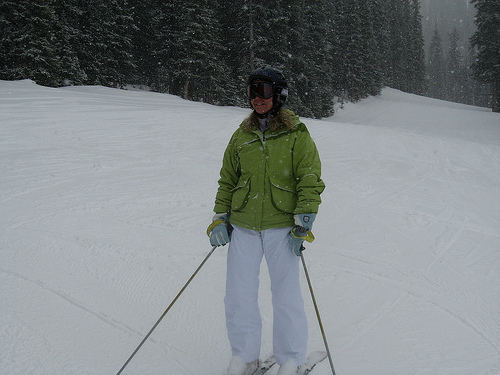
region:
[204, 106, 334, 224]
a green coat on a person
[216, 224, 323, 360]
white pants on a person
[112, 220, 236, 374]
a ski pole held in a hand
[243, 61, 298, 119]
a black helmet on a person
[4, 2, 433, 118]
a forest of pine trees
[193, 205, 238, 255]
a glove on a person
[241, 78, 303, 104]
goggles on a person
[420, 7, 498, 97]
snow falling in the distance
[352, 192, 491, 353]
tracks in the snow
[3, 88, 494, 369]
a white snowy slope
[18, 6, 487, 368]
A blistery winter day on the mountain.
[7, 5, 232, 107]
Evergreen trees growing in the woods.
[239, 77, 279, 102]
Ski mask for protecting her eyes.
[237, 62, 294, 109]
Black safety helmet for protection.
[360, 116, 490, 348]
Ground covered in layers of fallen snow.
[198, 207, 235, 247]
Light blue snow glove for keeping her hands warm.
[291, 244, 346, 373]
Tall ski pole to help get through the snow.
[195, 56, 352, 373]
Woman standing on two skis.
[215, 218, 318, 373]
Woman wearing white snow pants.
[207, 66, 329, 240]
Woman wearing puffy green snow jacket.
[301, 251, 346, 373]
a long trekking pole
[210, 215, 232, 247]
a gray ski glove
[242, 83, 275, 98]
dark black goggles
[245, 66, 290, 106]
a dark blue ski helmet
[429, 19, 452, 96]
a snow covered tree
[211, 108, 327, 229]
a woman's green coat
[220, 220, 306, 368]
a woman's white ski pants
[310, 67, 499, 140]
a section of white snow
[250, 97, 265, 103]
the nose of a woman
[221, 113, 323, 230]
green padded winter jacket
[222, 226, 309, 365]
white padded snow pants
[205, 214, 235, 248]
white and green glove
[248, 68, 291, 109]
black winter ski hat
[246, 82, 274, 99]
black sunglass ski goggles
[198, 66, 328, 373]
woman standing on skis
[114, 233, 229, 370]
black metal ski pole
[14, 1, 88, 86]
evergreen tree covered with snow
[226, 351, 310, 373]
white winter ski boots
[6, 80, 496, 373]
hill covered in snow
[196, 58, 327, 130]
a woman wearing ski goggles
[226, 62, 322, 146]
a woman wearing a black helmet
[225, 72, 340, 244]
a woman wearing a green ski jacket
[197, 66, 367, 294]
a woman wearing gloves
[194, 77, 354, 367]
a woman wearing white ski pants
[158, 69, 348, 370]
a woman skiing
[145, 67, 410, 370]
a woman holding ski poles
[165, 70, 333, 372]
a woman on skis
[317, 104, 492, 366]
white snow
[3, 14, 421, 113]
green trees with snow on them